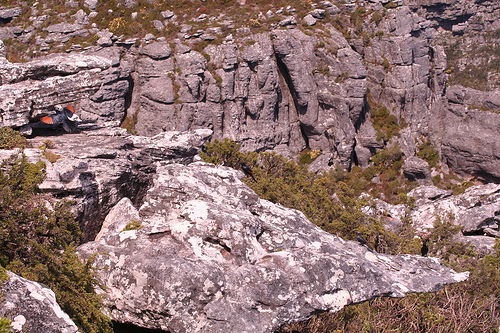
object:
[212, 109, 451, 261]
bushes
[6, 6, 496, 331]
rocks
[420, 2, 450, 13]
shadows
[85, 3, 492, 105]
cliff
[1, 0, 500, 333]
mountain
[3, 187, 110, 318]
grass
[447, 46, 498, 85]
green patch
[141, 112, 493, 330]
plants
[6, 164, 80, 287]
trees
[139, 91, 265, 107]
lines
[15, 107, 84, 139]
bear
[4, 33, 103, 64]
shrub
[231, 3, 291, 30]
shrub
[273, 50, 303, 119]
shadow